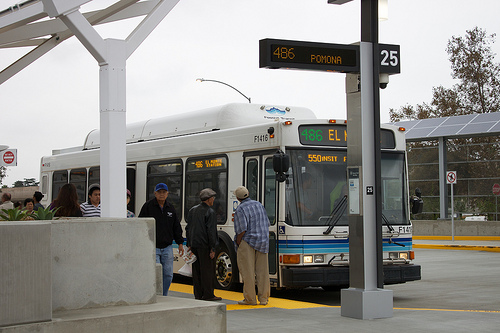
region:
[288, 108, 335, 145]
This is bus number 486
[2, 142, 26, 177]
Do not enter sign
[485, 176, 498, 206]
Stop sign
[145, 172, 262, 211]
Three men wearing hats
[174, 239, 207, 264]
Man is holding a newspaper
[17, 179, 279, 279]
Passengers waiting to board the bus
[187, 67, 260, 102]
Street light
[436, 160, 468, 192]
Do not walk sign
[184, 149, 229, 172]
Bus is traveling to El Monte station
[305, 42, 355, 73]
Bus is at Pomona station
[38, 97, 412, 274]
white large bus on bustation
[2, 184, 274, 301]
bunch of people in line two get the bus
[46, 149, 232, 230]
six big black windows on right side of the bus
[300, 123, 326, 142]
green number 486 on the screen at the top of the bus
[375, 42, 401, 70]
black signboard with white numers in it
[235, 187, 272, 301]
black with blue plaid shirt and sand pants standing in a side of the bus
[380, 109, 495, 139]
grey roof in the right side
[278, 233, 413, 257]
dar blue, medium blue and light blue line in front of the bus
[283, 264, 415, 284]
black bumper in front of the bus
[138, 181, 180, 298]
man standing at a side of the bus with blue cap and black t-shirt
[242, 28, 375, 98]
digital street sign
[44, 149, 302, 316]
group of people on the sidewalk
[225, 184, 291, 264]
man wearing a checkered shirt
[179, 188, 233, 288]
old man wearing a black jacket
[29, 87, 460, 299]
white and blue city bus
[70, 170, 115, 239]
man wearing a striped shirt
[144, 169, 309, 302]
three men wearing hats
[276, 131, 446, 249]
large bus windshield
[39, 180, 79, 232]
long brown hair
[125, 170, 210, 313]
man wearing blue jeans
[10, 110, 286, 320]
People waiting at a bus stop.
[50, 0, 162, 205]
One of the support beams for the roof.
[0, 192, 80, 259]
Two plants.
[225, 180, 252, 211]
The man is wearing a hat.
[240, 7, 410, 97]
An electric display with the name of the destination.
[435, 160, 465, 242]
A street sign.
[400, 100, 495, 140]
Solar panels.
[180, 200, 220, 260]
The man is wearing a jacket.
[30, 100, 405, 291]
A large white bus.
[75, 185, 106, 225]
The man is wearing a striped shirt.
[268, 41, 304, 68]
the numbers are yellow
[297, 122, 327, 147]
the numbers are green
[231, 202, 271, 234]
the shirt is blue and white plaid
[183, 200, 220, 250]
the jacket is black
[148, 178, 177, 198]
the hat is blue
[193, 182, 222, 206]
the hat is grey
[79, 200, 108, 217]
the shirt is white and black stripes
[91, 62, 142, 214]
the pillar is white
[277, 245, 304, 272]
the light cover is orange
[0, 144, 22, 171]
the sign is white and red